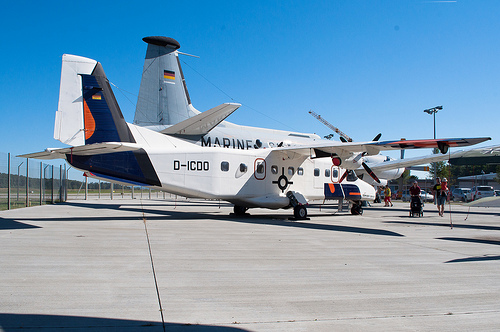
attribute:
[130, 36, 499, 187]
gray plane — large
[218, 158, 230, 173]
window — passenger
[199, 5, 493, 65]
sky — very blue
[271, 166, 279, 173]
passenger window — white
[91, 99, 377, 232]
plane — white 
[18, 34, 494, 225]
airplane — white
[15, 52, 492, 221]
plane — white, blue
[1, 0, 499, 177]
sky — clear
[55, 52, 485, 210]
plane — white